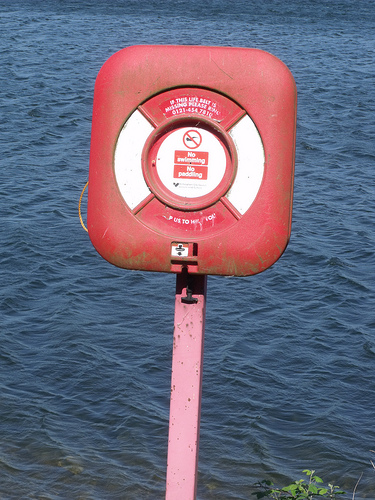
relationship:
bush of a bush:
[246, 466, 342, 499] [267, 466, 338, 494]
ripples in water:
[236, 362, 290, 392] [236, 334, 323, 442]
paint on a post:
[169, 306, 194, 481] [155, 278, 214, 482]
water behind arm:
[0, 0, 375, 500] [163, 277, 208, 500]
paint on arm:
[163, 277, 208, 500] [163, 277, 208, 500]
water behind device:
[17, 50, 84, 253] [83, 36, 301, 498]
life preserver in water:
[73, 41, 302, 282] [0, 0, 375, 500]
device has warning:
[179, 126, 206, 151] [108, 78, 271, 243]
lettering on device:
[160, 93, 227, 119] [161, 93, 225, 119]